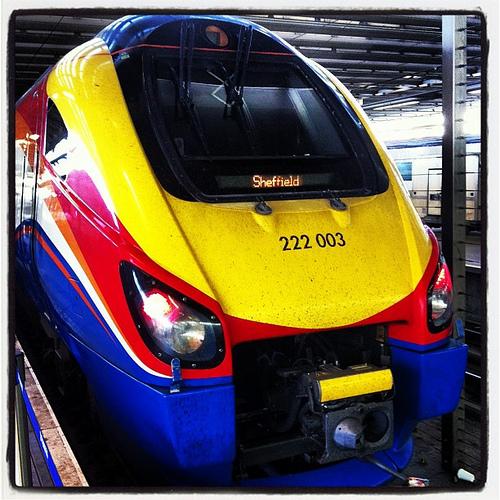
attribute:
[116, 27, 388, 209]
window — black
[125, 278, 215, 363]
headlight — right front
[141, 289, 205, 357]
headlight — black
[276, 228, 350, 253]
numbers — black, printed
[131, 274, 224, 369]
light — black, train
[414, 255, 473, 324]
light — black, head, train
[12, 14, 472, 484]
train — red, head, electric